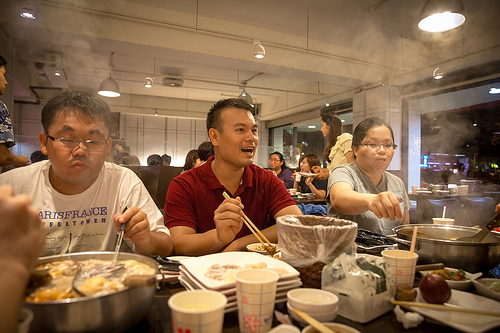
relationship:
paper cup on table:
[167, 289, 230, 330] [1, 245, 499, 332]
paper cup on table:
[235, 268, 276, 329] [1, 245, 499, 332]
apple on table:
[420, 272, 451, 304] [1, 245, 499, 332]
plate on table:
[180, 251, 300, 292] [1, 245, 499, 332]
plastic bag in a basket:
[276, 214, 357, 266] [276, 213, 357, 287]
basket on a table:
[276, 213, 357, 287] [1, 245, 499, 332]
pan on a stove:
[428, 188, 450, 196] [408, 184, 496, 220]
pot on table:
[391, 224, 498, 266] [1, 245, 499, 332]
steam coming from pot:
[315, 11, 480, 207] [391, 224, 498, 266]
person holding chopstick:
[166, 97, 302, 254] [221, 188, 275, 250]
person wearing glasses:
[326, 115, 412, 234] [358, 140, 398, 153]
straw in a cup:
[443, 204, 447, 218] [433, 216, 454, 224]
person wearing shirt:
[166, 97, 302, 254] [166, 154, 294, 239]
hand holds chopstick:
[212, 195, 245, 243] [221, 188, 275, 250]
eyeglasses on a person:
[44, 131, 111, 152] [2, 84, 174, 257]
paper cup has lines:
[167, 289, 230, 330] [171, 316, 218, 328]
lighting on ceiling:
[252, 37, 266, 60] [6, 1, 495, 118]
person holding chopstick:
[2, 84, 174, 257] [221, 188, 275, 250]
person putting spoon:
[2, 84, 174, 257] [113, 208, 128, 268]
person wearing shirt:
[2, 84, 174, 257] [166, 154, 294, 239]